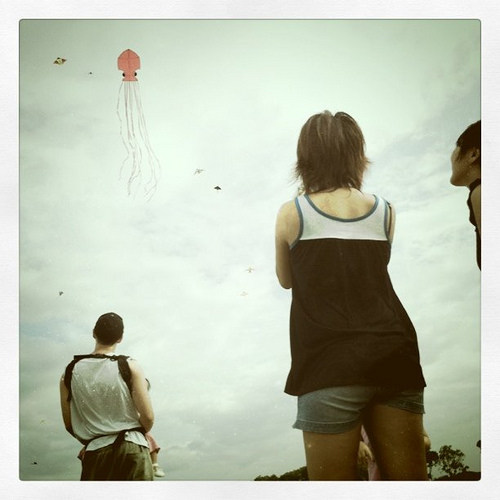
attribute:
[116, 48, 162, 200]
kite — pink, octopus, red, orange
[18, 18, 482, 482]
sky — cloudy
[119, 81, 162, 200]
tail — pink, long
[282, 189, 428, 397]
tank top — white, black, brown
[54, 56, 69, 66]
kite — red, orange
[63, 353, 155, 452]
tee shirt — cotton, white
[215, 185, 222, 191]
kite — black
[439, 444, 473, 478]
leaves — green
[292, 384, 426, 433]
shorts — short, grey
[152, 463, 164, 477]
shoe — white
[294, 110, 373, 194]
hair — brown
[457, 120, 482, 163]
hair — brown